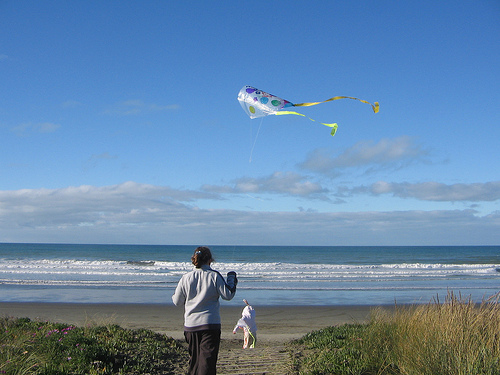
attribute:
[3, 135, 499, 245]
clouds — stratus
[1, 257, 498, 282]
cap — white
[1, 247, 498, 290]
wave — crashing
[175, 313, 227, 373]
pants — black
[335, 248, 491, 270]
water — blue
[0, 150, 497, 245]
clouds — low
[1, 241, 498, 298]
ocean — large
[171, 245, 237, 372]
woman — long sleeved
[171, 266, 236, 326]
shirt — gray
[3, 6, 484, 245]
sky — blue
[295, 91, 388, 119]
kite tail — yellow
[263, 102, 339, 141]
kite tail — yellow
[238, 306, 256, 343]
cloths — white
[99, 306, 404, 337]
dunes — sand